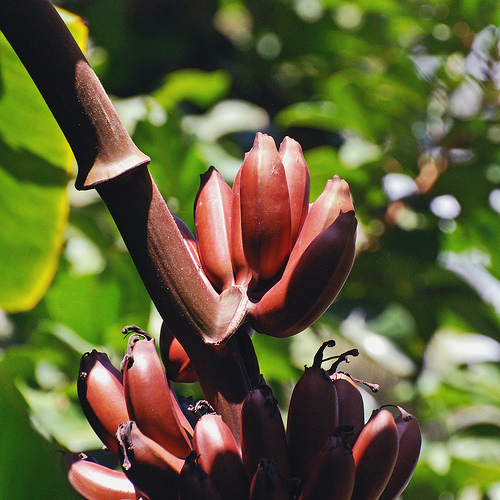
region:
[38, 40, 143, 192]
brown plant stem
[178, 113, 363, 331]
small brown banana bunch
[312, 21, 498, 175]
trees with green leaves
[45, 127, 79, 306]
yellow edge on green leaf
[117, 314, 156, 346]
small brown stem on end of banana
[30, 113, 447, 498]
bunches of brown bananas on tree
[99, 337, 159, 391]
sunlight reflecting on brown banana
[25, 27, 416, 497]
banana bunches on brown stem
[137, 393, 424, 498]
bunch of bananas covered in shadow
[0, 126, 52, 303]
large green banana tree leaf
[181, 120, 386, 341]
red bananas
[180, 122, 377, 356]
a cluster of fruit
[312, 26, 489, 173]
green leaves blurred in the background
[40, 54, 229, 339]
fruit is growing on a red stem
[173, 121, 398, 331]
sun shining on bananas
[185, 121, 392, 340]
a cluster of at least 6 bananas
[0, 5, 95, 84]
shaded area of the stem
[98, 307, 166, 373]
remnants of the flower bloom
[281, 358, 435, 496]
area of shadow on the banana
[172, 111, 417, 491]
daylight shining on the fruit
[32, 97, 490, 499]
bananas that are outside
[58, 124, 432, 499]
bananas that are growing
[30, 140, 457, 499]
bananas on a tree branch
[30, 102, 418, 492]
bananas growing on a tree branch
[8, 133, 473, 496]
bananas growing on a branch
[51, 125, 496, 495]
a branch with a bunch of bananas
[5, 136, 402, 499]
bananas that are a red color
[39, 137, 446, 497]
bananas that are red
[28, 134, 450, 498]
branch with red bananas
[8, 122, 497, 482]
fruit no a branch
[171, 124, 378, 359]
red smooth small bananas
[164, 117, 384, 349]
bananas sticking up on the air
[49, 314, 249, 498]
sun light hitting red bananas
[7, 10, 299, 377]
brown banana branch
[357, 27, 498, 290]
blurry forest green in the backgrown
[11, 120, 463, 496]
lots of red bananas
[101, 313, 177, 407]
dried peal end on top of banana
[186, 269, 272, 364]
curved on of banana branch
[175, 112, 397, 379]
bananas stucked together in on tree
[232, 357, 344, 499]
silhouettes of small bananas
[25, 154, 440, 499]
The plant is red.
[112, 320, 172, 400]
The plant is opening.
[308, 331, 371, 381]
The flowers are black.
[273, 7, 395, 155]
The leaves are green.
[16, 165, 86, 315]
Yellow on the leave.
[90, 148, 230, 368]
The branch is brown.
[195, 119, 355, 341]
Flowers are completely closed.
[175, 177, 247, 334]
Light shining on the plant.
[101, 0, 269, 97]
Dark green in the background.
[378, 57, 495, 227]
Sun shining through the leaves.